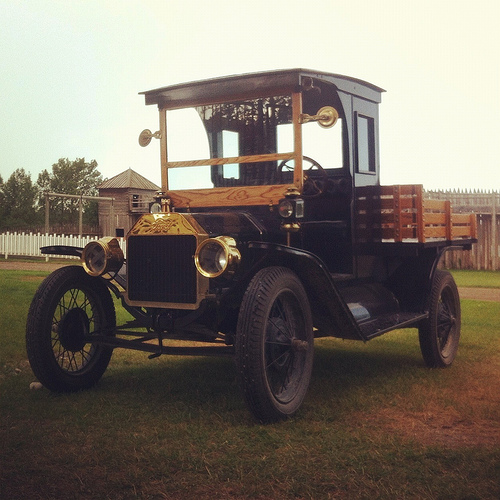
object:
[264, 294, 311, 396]
spokes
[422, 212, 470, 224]
slats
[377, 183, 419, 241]
tailgate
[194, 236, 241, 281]
headlight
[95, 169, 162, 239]
building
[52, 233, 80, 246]
fence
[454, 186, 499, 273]
fence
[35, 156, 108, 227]
trees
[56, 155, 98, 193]
leaves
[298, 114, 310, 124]
car mirror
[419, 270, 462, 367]
tire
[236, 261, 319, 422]
tire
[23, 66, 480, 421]
antique car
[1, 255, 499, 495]
ground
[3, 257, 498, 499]
grass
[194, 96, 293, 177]
curtain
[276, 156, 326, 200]
steering wheel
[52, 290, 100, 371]
spokes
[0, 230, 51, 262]
fence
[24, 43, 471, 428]
truck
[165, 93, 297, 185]
window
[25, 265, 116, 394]
tire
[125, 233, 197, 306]
grill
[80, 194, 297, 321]
car front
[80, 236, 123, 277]
headlight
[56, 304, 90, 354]
plate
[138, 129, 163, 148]
mirror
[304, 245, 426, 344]
step